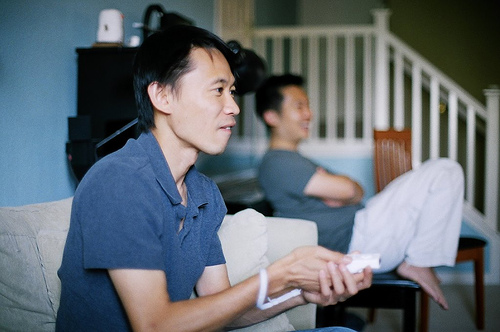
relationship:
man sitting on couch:
[50, 20, 378, 331] [0, 192, 324, 332]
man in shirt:
[50, 20, 378, 331] [51, 123, 232, 331]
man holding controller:
[50, 20, 378, 331] [252, 250, 387, 313]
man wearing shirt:
[250, 69, 468, 312] [252, 146, 368, 257]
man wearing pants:
[250, 69, 468, 312] [343, 155, 470, 278]